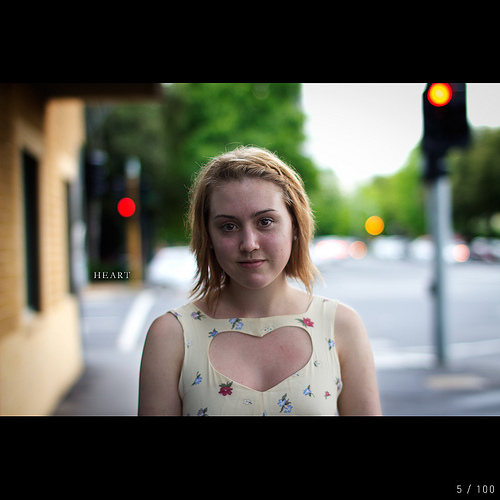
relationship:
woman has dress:
[134, 140, 387, 418] [167, 288, 345, 417]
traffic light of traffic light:
[117, 197, 137, 219] [113, 178, 146, 224]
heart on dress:
[204, 328, 315, 395] [167, 288, 345, 417]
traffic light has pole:
[414, 81, 478, 189] [420, 175, 456, 370]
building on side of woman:
[2, 74, 168, 416] [2, 75, 193, 421]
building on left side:
[2, 74, 168, 416] [2, 78, 142, 418]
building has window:
[2, 74, 168, 416] [6, 114, 53, 318]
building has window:
[2, 74, 168, 416] [55, 152, 82, 298]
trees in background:
[92, 78, 496, 244] [77, 82, 499, 351]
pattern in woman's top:
[204, 328, 315, 395] [167, 288, 345, 417]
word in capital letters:
[91, 266, 136, 283] [89, 267, 134, 281]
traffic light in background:
[117, 197, 137, 219] [77, 82, 499, 351]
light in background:
[425, 82, 455, 110] [77, 82, 499, 351]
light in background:
[362, 213, 387, 238] [77, 82, 499, 351]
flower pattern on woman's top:
[270, 391, 295, 416] [167, 288, 345, 417]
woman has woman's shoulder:
[134, 140, 387, 418] [144, 290, 223, 359]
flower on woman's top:
[217, 380, 236, 401] [167, 288, 345, 417]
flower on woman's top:
[295, 314, 318, 332] [167, 288, 345, 417]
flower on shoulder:
[295, 314, 318, 332] [289, 285, 364, 338]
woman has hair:
[134, 140, 387, 418] [186, 144, 327, 317]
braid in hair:
[235, 160, 287, 184] [186, 144, 327, 317]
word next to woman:
[91, 266, 136, 283] [134, 140, 387, 418]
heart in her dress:
[204, 328, 315, 395] [167, 288, 345, 417]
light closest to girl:
[425, 82, 455, 110] [134, 140, 387, 418]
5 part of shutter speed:
[451, 477, 468, 498] [447, 477, 498, 498]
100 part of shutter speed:
[469, 475, 497, 495] [447, 477, 498, 498]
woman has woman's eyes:
[134, 140, 387, 418] [215, 215, 277, 236]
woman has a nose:
[134, 140, 387, 418] [233, 226, 262, 254]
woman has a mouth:
[134, 140, 387, 418] [233, 255, 272, 272]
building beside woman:
[2, 74, 168, 416] [134, 140, 387, 418]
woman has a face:
[134, 140, 387, 418] [204, 176, 298, 294]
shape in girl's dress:
[204, 328, 315, 395] [167, 288, 345, 417]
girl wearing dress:
[134, 140, 387, 418] [167, 288, 345, 417]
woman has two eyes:
[134, 140, 387, 418] [215, 215, 277, 236]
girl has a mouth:
[134, 140, 387, 418] [233, 255, 272, 272]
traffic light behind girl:
[113, 178, 146, 224] [134, 140, 387, 418]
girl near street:
[134, 140, 387, 418] [77, 234, 497, 423]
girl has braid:
[134, 140, 387, 418] [235, 160, 287, 184]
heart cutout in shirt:
[204, 328, 315, 395] [167, 288, 345, 417]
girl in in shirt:
[134, 140, 387, 418] [167, 288, 345, 417]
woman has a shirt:
[134, 140, 387, 418] [167, 288, 345, 417]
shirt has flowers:
[167, 288, 345, 417] [169, 306, 343, 417]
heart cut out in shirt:
[204, 328, 315, 395] [167, 288, 345, 417]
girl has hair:
[134, 140, 387, 418] [186, 144, 327, 317]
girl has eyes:
[134, 140, 387, 418] [216, 217, 283, 230]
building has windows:
[2, 74, 168, 416] [8, 118, 75, 317]